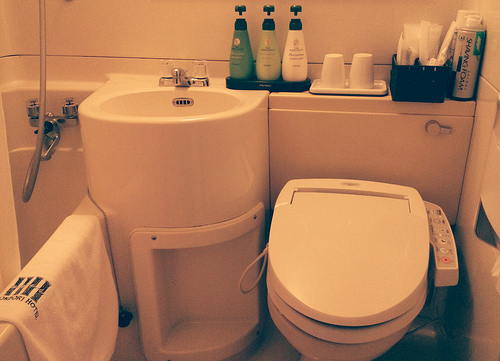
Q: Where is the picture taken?
A: A bathroom.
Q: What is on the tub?
A: Towel.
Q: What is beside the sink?
A: Toilet.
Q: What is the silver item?
A: Faucet.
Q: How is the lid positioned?
A: Down.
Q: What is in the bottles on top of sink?
A: Lotion.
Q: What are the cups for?
A: Water.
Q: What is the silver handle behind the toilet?
A: Flush knob.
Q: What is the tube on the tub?
A: Shower head.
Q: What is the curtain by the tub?
A: Shower curtain.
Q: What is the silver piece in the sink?
A: Drain.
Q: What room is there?
A: Bathroom.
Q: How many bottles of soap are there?
A: Three.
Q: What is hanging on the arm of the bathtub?
A: Towel.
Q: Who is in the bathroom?
A: No one.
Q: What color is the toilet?
A: White.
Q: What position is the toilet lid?
A: Closed.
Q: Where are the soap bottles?
A: Sink.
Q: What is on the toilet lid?
A: Cups.